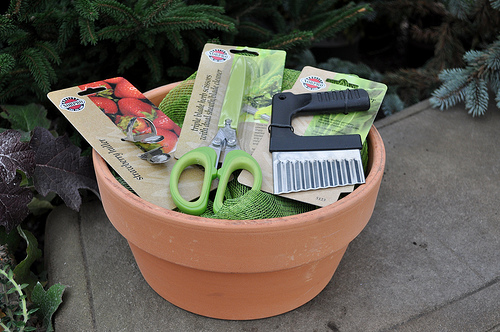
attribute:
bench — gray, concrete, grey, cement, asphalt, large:
[44, 82, 499, 331]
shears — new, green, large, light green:
[168, 53, 261, 218]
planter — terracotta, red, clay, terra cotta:
[93, 79, 387, 322]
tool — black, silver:
[270, 90, 371, 198]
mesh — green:
[109, 66, 372, 220]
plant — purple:
[26, 126, 100, 212]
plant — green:
[29, 281, 67, 332]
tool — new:
[44, 77, 234, 212]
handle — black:
[268, 86, 371, 151]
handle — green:
[172, 141, 265, 218]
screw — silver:
[212, 138, 222, 148]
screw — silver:
[226, 137, 236, 147]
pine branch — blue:
[465, 77, 489, 114]